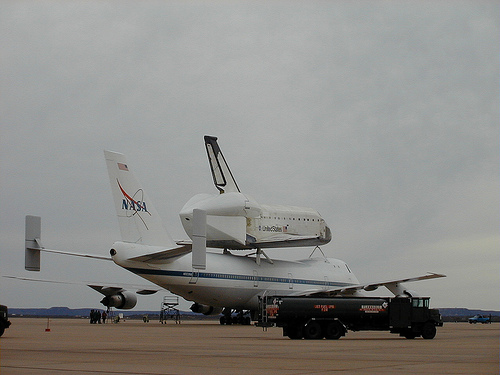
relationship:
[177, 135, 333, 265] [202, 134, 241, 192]
plane with tail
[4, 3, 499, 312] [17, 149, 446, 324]
sky over airplane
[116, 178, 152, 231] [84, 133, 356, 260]
logo on plane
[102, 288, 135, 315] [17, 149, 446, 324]
turbine for a airplane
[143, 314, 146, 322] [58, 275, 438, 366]
people standing on concrete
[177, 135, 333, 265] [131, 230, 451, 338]
plane riding piggy back on airplane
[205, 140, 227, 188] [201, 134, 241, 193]
rectangle on tail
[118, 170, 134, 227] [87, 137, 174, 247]
logo on tail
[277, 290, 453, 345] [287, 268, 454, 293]
truck close to wing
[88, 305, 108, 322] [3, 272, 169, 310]
people standing under wing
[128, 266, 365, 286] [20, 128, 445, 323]
dark stripe along length plane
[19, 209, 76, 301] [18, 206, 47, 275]
pole with rectangle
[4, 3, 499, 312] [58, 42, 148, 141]
sky has section